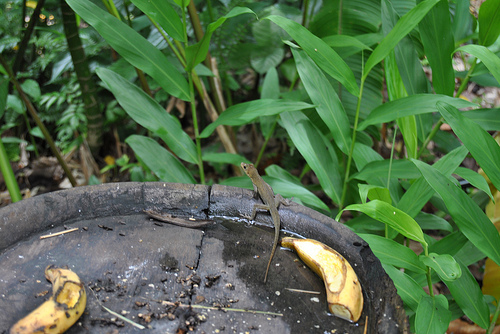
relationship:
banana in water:
[278, 234, 366, 323] [285, 269, 305, 282]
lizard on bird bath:
[233, 160, 298, 288] [5, 178, 388, 333]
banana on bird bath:
[12, 249, 88, 331] [5, 178, 388, 333]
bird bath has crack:
[5, 178, 388, 333] [179, 190, 207, 313]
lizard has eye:
[233, 160, 298, 288] [241, 165, 247, 170]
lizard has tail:
[233, 160, 298, 288] [265, 221, 283, 285]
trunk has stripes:
[53, 0, 107, 166] [69, 46, 87, 66]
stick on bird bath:
[33, 219, 90, 248] [5, 178, 388, 333]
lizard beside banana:
[233, 160, 298, 288] [278, 234, 366, 323]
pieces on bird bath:
[122, 268, 235, 331] [5, 178, 388, 333]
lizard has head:
[233, 160, 298, 288] [238, 160, 261, 178]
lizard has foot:
[233, 160, 298, 288] [280, 195, 300, 210]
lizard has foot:
[233, 160, 298, 288] [238, 210, 253, 224]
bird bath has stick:
[5, 178, 388, 333] [282, 279, 324, 297]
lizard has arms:
[233, 160, 298, 288] [247, 176, 280, 197]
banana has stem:
[278, 234, 366, 323] [280, 233, 298, 251]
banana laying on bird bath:
[285, 230, 375, 320] [0, 178, 413, 333]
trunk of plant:
[45, 17, 139, 149] [45, 17, 139, 149]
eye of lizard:
[235, 157, 276, 198] [235, 157, 276, 198]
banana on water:
[278, 234, 366, 323] [256, 231, 393, 311]